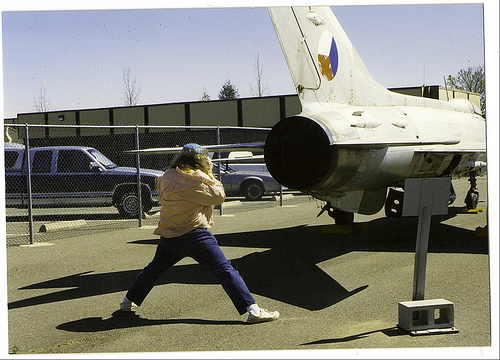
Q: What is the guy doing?
A: Spreading legs.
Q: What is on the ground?
A: Shadow.